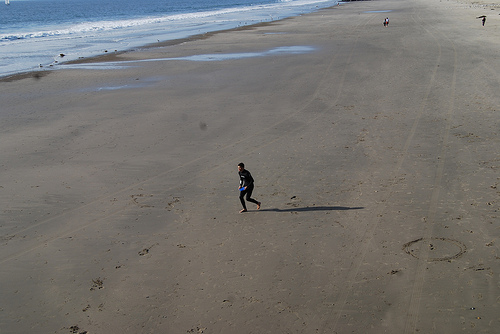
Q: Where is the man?
A: On the beach.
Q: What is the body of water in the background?
A: Ocean.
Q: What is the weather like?
A: Sunny.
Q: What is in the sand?
A: Footprints.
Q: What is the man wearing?
A: Wetsuit.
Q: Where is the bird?
A: Right corner of scene.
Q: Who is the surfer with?
A: By himself.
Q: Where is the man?
A: On the beach.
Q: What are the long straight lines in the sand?
A: Tire tracks.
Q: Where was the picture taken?
A: Beach.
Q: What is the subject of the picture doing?
A: Running.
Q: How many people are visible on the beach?
A: Three.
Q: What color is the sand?
A: Brown.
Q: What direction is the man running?
A: Left.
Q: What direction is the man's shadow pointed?
A: Right.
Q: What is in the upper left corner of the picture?
A: Ocean.